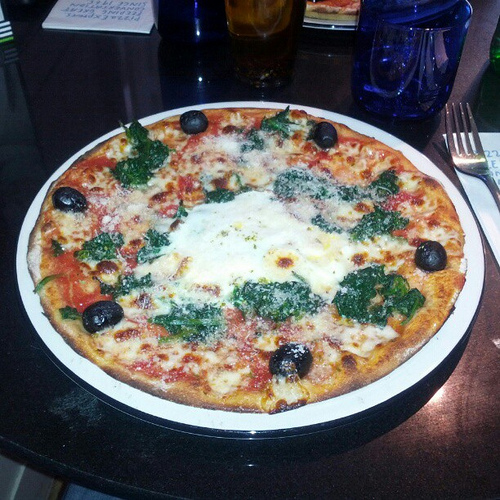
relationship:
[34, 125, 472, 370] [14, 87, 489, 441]
pizza on plate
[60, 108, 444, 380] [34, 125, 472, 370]
olives on pizza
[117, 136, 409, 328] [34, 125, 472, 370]
vegetables on pizza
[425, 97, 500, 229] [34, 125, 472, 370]
fork next to pizza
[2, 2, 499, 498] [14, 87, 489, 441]
table under plate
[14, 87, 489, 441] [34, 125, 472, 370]
plate under pizza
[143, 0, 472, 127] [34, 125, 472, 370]
glasses behind pizza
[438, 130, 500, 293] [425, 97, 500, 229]
napkin under fork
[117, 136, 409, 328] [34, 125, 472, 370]
vegetables atop pizza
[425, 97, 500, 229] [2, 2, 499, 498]
fork on table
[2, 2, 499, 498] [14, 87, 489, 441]
table underneath plate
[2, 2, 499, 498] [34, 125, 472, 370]
table underneath pizza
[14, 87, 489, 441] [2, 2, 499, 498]
plate on table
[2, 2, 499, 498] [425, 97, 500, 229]
table underneath fork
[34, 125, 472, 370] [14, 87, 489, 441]
pizza atop plate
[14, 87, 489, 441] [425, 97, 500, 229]
plate near fork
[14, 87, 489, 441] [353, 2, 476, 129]
plate near cup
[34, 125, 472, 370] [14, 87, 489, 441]
pizza on top of plate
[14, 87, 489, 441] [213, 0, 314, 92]
plate near glass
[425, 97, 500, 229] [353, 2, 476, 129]
fork near cup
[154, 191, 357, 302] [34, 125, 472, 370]
cheese on pizza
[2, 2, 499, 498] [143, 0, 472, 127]
table underneath glasses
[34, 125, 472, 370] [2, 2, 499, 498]
pizza placed on table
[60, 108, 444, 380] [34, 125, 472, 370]
olives on top of pizza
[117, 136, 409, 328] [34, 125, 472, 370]
vegetables on top of pizza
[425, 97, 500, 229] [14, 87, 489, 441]
fork next to plate